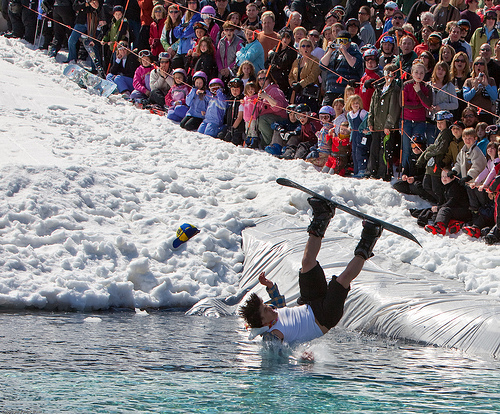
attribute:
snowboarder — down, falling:
[244, 176, 423, 365]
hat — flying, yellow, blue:
[168, 224, 200, 247]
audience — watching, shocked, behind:
[5, 4, 499, 239]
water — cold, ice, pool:
[8, 307, 499, 413]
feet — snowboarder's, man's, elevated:
[304, 199, 386, 252]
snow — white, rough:
[4, 38, 497, 313]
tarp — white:
[238, 219, 499, 360]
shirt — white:
[272, 302, 320, 342]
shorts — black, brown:
[296, 262, 352, 329]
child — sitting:
[173, 72, 226, 132]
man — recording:
[321, 30, 357, 121]